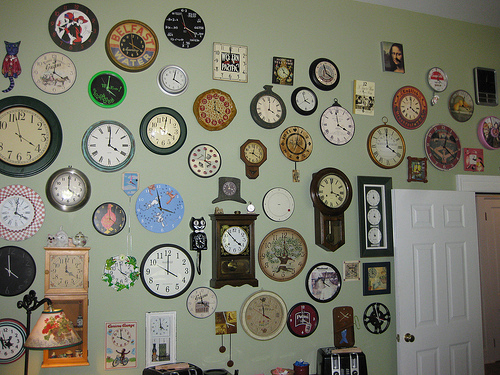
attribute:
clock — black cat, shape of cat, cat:
[188, 215, 213, 276]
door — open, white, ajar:
[390, 184, 492, 375]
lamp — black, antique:
[16, 290, 82, 374]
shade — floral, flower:
[21, 307, 88, 356]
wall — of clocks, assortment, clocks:
[2, 2, 500, 375]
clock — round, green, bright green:
[86, 67, 128, 111]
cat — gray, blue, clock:
[1, 36, 27, 94]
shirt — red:
[1, 54, 21, 76]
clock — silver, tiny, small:
[156, 63, 189, 98]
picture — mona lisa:
[380, 36, 407, 75]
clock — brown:
[190, 84, 235, 131]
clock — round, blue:
[131, 184, 187, 241]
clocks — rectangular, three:
[356, 170, 396, 258]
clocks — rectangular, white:
[141, 308, 179, 368]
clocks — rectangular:
[39, 235, 94, 371]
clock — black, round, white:
[160, 5, 206, 54]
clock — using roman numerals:
[309, 168, 354, 253]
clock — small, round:
[426, 65, 448, 96]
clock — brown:
[277, 126, 315, 166]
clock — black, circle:
[1, 242, 38, 301]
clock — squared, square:
[208, 41, 250, 84]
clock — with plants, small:
[98, 250, 140, 293]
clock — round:
[45, 2, 101, 53]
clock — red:
[292, 86, 318, 119]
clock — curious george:
[103, 321, 141, 372]